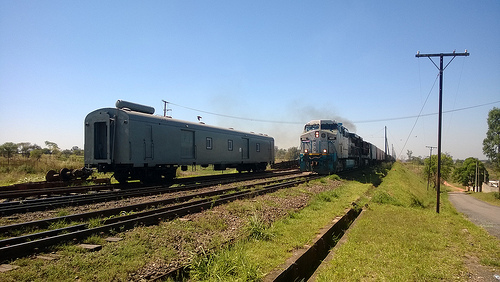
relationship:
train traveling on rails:
[296, 110, 389, 171] [2, 135, 331, 256]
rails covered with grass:
[2, 135, 331, 256] [10, 171, 307, 242]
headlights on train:
[302, 131, 333, 154] [296, 110, 389, 171]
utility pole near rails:
[416, 49, 466, 222] [2, 135, 331, 256]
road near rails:
[436, 171, 499, 240] [2, 135, 331, 256]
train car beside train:
[83, 99, 280, 188] [296, 110, 389, 171]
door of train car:
[94, 122, 109, 160] [83, 99, 280, 188]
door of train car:
[181, 130, 199, 162] [83, 99, 280, 188]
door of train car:
[242, 137, 252, 159] [83, 99, 280, 188]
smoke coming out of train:
[333, 116, 358, 135] [296, 110, 389, 171]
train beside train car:
[296, 110, 389, 171] [83, 99, 280, 188]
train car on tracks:
[83, 99, 280, 188] [4, 152, 289, 218]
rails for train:
[2, 135, 331, 256] [296, 110, 389, 171]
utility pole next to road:
[416, 49, 466, 222] [436, 171, 499, 240]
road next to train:
[436, 171, 499, 240] [296, 110, 389, 171]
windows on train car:
[203, 137, 265, 153] [83, 99, 280, 188]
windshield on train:
[303, 118, 339, 131] [296, 110, 389, 171]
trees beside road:
[434, 105, 500, 194] [436, 171, 499, 240]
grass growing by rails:
[238, 150, 444, 281] [2, 135, 331, 256]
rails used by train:
[2, 135, 331, 256] [296, 110, 389, 171]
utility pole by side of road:
[416, 49, 466, 222] [436, 171, 499, 240]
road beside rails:
[436, 171, 499, 240] [2, 135, 331, 256]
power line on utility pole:
[352, 36, 496, 159] [416, 49, 466, 222]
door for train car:
[94, 122, 109, 160] [83, 99, 280, 188]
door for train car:
[181, 130, 199, 162] [83, 99, 280, 188]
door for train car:
[242, 137, 252, 159] [83, 99, 280, 188]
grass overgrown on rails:
[10, 171, 307, 242] [2, 135, 331, 256]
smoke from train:
[333, 116, 358, 135] [296, 110, 389, 171]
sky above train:
[1, 1, 500, 154] [296, 110, 389, 171]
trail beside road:
[436, 178, 468, 192] [436, 171, 499, 240]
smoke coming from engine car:
[333, 116, 358, 135] [301, 113, 358, 174]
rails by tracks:
[2, 135, 331, 256] [4, 152, 289, 218]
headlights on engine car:
[302, 131, 333, 154] [301, 113, 358, 174]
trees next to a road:
[434, 105, 500, 194] [436, 171, 499, 240]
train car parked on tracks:
[83, 99, 280, 188] [4, 152, 289, 218]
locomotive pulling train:
[79, 96, 279, 175] [294, 115, 397, 175]